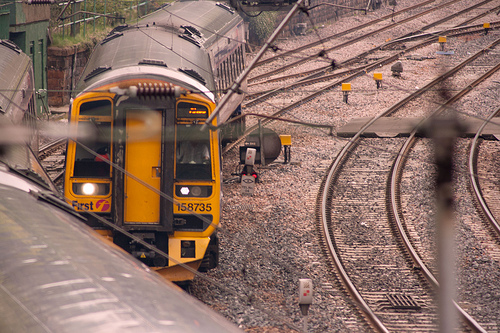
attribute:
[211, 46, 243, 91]
window — side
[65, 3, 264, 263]
train — YELLOW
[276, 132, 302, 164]
bumps — arranged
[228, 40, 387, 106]
cables — electric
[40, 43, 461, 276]
station — railway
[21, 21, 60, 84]
hut — metal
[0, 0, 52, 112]
hut — green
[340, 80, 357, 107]
bumps — yellow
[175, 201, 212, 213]
numbers — written, black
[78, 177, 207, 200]
train lights — head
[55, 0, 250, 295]
train — black, yellow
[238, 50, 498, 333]
stone — crushed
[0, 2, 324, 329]
station — railway